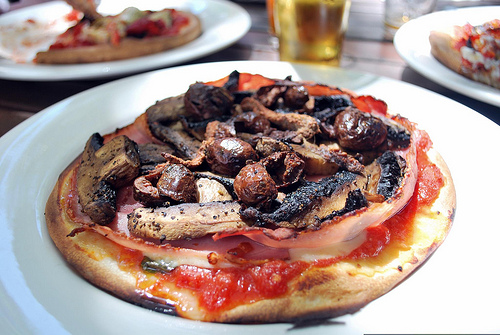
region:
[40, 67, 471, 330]
A fully cooked pizza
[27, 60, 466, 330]
Pizza is in the foreground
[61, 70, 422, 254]
Mushrooms are main pizza topping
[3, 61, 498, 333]
Pizza is on a white plate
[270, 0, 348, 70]
A glass cup in the background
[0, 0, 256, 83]
A pizza in the background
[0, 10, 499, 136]
Plates are on the table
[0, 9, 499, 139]
Table is made of wood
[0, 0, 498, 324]
Three pizzas in the image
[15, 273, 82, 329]
A crisp white plate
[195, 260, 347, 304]
A red pizza patch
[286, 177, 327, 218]
A black pizza decoration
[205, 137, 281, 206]
Tasty looking meat balls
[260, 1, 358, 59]
A fluid filled mug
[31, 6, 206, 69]
A half eaten pizza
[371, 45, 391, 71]
A brown shiny table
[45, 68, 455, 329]
A big stocked pizza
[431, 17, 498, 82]
A plateful of pizza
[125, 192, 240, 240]
A cumin decorated pizza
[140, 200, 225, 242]
mushrooms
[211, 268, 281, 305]
sauce on the pizza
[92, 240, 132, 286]
the crust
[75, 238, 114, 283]
the crust is brown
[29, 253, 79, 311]
the plate is white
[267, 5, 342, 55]
a glass on the table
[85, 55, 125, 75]
rim of the plate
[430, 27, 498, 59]
pizza on the plate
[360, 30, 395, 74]
the table is brown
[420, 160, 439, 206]
the red sauce on the pizza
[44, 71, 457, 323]
a delicious meat pizza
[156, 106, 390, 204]
four meatballs on pizza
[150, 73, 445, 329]
lots of tomato sauce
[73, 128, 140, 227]
brown burnt mushroom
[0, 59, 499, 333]
large round white plate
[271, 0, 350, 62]
a glass of drink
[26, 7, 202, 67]
a large slice of pizza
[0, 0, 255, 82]
a small round plate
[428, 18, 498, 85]
a small slice of pizza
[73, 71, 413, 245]
a bunch of burnt pizza toppings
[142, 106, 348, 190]
the meat is brown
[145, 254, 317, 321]
sauce is on the pizza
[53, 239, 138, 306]
the crust is brown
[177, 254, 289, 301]
tomatoe s are on the crust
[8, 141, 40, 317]
the plate is white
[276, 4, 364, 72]
the glass is half full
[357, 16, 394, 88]
the table is wooden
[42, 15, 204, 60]
the pizza is half eaten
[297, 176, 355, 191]
the crust is black